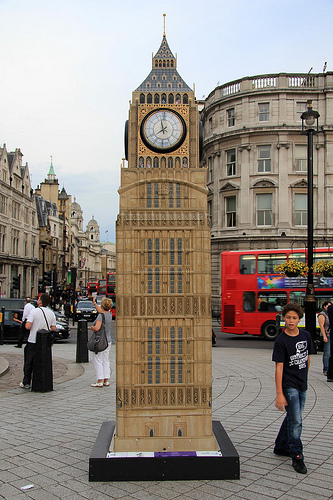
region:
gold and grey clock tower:
[101, 9, 225, 459]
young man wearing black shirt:
[266, 302, 316, 478]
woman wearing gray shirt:
[85, 292, 115, 389]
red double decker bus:
[217, 246, 332, 341]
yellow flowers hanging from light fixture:
[271, 252, 332, 281]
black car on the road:
[69, 299, 97, 319]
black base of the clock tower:
[86, 414, 236, 481]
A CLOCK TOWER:
[85, 10, 241, 482]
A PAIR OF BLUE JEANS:
[270, 385, 309, 458]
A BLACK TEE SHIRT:
[270, 326, 314, 393]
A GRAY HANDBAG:
[85, 309, 111, 354]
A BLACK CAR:
[0, 306, 72, 344]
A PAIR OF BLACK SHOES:
[272, 444, 310, 475]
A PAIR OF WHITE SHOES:
[89, 378, 112, 388]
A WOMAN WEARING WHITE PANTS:
[83, 290, 114, 389]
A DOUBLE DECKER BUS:
[218, 245, 331, 342]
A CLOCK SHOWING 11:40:
[137, 106, 189, 155]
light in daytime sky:
[0, 0, 331, 238]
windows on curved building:
[209, 99, 312, 232]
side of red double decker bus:
[220, 247, 330, 338]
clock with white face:
[143, 110, 183, 149]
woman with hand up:
[89, 296, 113, 386]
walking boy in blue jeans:
[272, 304, 313, 474]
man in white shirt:
[20, 295, 56, 388]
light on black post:
[299, 100, 321, 351]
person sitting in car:
[1, 309, 21, 340]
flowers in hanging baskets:
[278, 259, 332, 277]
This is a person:
[270, 295, 312, 476]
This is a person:
[316, 294, 331, 384]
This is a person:
[83, 286, 120, 399]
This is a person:
[31, 290, 64, 397]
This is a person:
[18, 293, 35, 352]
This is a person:
[65, 294, 78, 335]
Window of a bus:
[235, 251, 256, 275]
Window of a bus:
[256, 252, 288, 274]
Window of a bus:
[288, 250, 306, 272]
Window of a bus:
[256, 289, 288, 311]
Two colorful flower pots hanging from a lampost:
[272, 257, 331, 277]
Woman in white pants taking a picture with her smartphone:
[89, 294, 112, 386]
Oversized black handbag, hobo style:
[85, 311, 107, 354]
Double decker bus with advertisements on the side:
[219, 248, 331, 341]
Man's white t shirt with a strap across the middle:
[24, 306, 56, 345]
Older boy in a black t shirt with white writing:
[271, 329, 310, 392]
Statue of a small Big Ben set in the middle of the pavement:
[113, 10, 211, 450]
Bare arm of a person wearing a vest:
[317, 313, 326, 342]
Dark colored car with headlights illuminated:
[71, 298, 96, 322]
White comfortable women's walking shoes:
[89, 379, 110, 387]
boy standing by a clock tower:
[271, 300, 319, 480]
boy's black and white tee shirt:
[270, 326, 312, 392]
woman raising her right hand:
[84, 288, 118, 389]